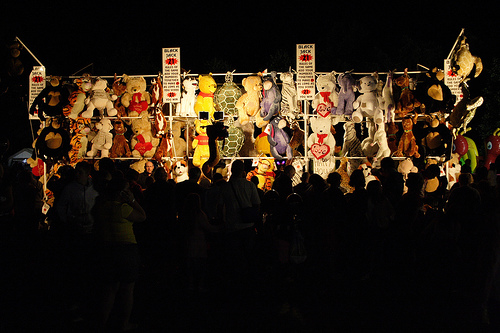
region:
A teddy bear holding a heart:
[115, 70, 150, 115]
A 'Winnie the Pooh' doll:
[190, 70, 220, 120]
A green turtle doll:
[210, 65, 240, 115]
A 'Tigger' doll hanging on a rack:
[55, 70, 90, 115]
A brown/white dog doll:
[160, 150, 190, 180]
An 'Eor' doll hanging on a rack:
[260, 105, 295, 160]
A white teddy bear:
[305, 110, 331, 160]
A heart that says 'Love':
[305, 135, 330, 155]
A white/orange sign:
[290, 35, 315, 97]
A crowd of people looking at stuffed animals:
[10, 153, 496, 329]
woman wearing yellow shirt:
[102, 177, 143, 312]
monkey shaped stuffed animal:
[32, 73, 67, 118]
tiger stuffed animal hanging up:
[66, 74, 91, 118]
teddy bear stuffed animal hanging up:
[123, 71, 153, 119]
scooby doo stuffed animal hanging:
[110, 121, 131, 164]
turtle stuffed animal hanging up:
[218, 73, 241, 114]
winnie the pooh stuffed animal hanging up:
[195, 67, 218, 117]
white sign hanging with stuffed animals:
[163, 47, 182, 101]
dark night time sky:
[148, 8, 248, 46]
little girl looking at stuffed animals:
[181, 193, 211, 288]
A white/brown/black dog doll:
[165, 155, 195, 180]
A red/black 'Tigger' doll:
[57, 70, 92, 120]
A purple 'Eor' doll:
[261, 110, 291, 155]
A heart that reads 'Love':
[305, 140, 330, 156]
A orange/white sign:
[155, 40, 187, 110]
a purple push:
[263, 114, 295, 163]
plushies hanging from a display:
[12, 25, 493, 216]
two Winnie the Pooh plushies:
[188, 70, 213, 182]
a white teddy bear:
[297, 111, 335, 166]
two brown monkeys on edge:
[23, 68, 73, 171]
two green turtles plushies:
[211, 67, 243, 177]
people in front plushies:
[5, 65, 495, 325]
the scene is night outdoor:
[0, 0, 495, 326]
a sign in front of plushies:
[155, 40, 185, 110]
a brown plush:
[84, 118, 114, 163]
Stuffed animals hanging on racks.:
[12, 31, 493, 221]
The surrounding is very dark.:
[6, 5, 492, 41]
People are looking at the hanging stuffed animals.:
[47, 158, 470, 288]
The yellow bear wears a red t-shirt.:
[192, 132, 211, 148]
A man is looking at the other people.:
[142, 160, 157, 176]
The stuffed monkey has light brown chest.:
[25, 70, 61, 126]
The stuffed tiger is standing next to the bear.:
[65, 70, 93, 120]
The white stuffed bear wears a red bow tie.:
[308, 112, 335, 164]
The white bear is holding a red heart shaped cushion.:
[305, 115, 335, 157]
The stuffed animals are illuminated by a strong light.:
[32, 57, 497, 208]